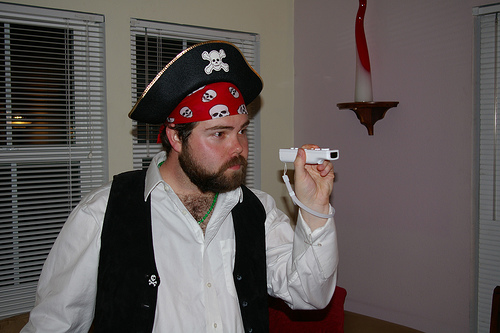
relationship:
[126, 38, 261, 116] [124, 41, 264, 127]
trim on a hat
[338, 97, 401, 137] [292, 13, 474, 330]
shelf on a wall